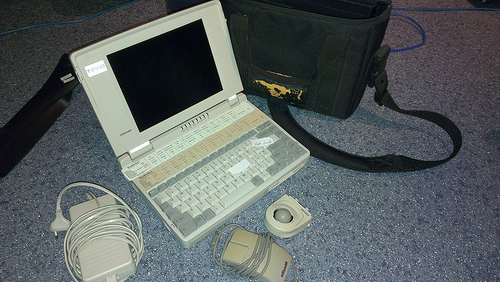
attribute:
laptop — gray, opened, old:
[59, 0, 331, 246]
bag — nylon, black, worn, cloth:
[226, 2, 392, 119]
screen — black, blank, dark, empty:
[99, 18, 220, 134]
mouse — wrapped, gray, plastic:
[215, 232, 289, 282]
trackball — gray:
[266, 192, 311, 239]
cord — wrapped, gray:
[79, 215, 111, 231]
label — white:
[79, 62, 110, 82]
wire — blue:
[7, 3, 124, 40]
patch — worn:
[245, 70, 308, 103]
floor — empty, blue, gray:
[8, 69, 492, 281]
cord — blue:
[17, 3, 135, 36]